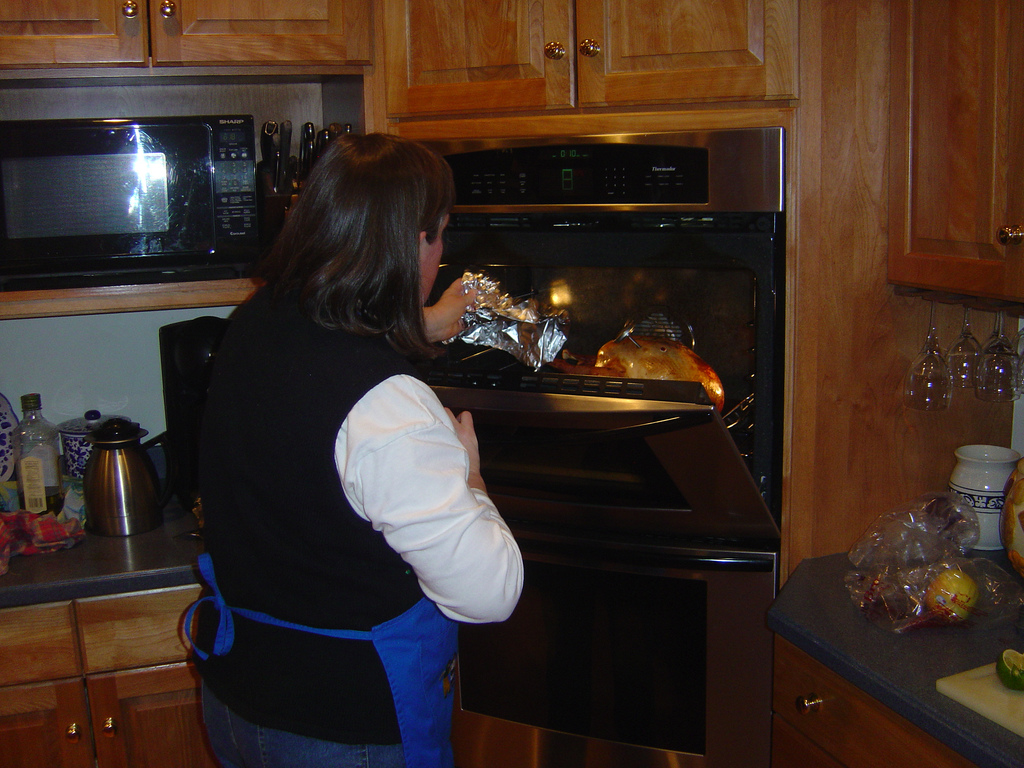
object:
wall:
[0, 306, 239, 447]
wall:
[789, 0, 896, 578]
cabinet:
[0, 660, 224, 768]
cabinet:
[384, 0, 800, 118]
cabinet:
[889, 0, 1024, 304]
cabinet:
[0, 0, 375, 70]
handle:
[796, 692, 823, 714]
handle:
[996, 224, 1023, 246]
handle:
[580, 38, 600, 57]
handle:
[544, 41, 564, 60]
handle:
[96, 711, 120, 731]